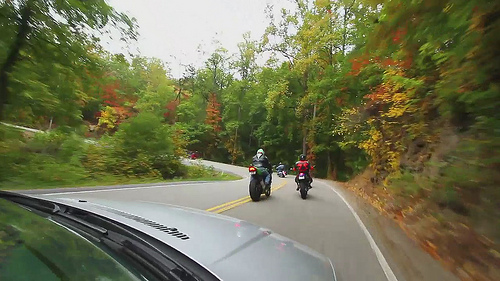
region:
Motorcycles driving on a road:
[241, 145, 316, 203]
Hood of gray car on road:
[64, 195, 341, 275]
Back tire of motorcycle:
[246, 181, 262, 198]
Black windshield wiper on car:
[10, 195, 110, 235]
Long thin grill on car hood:
[74, 197, 187, 240]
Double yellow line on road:
[207, 175, 284, 212]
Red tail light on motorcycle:
[247, 167, 255, 174]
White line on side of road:
[342, 193, 392, 279]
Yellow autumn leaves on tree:
[385, 93, 415, 123]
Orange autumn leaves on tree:
[206, 91, 219, 133]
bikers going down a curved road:
[240, 136, 317, 217]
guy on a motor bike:
[244, 143, 274, 205]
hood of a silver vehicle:
[30, 188, 332, 280]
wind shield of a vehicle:
[2, 191, 148, 278]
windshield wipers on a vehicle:
[20, 192, 197, 279]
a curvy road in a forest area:
[0, 111, 387, 280]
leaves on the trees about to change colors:
[336, 23, 418, 127]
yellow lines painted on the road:
[197, 163, 300, 217]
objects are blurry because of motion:
[339, 142, 493, 274]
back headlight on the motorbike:
[247, 164, 260, 171]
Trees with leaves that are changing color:
[6, 2, 498, 276]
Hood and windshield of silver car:
[2, 184, 336, 277]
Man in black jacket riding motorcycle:
[243, 147, 274, 199]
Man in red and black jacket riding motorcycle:
[288, 152, 317, 199]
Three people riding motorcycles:
[243, 140, 316, 204]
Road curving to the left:
[3, 113, 398, 278]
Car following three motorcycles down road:
[4, 116, 397, 280]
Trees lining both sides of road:
[3, 3, 498, 277]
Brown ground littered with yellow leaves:
[346, 163, 498, 278]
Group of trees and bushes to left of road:
[6, 37, 239, 185]